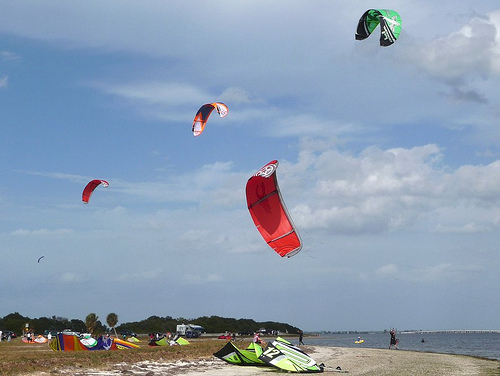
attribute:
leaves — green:
[91, 300, 118, 349]